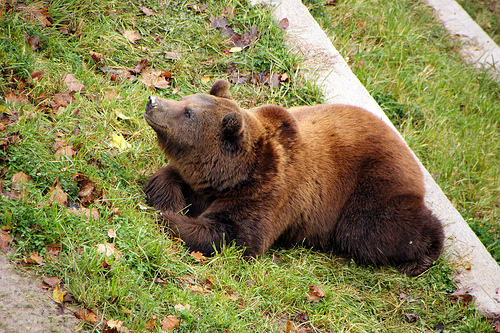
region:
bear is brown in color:
[142, 99, 431, 254]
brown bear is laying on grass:
[138, 91, 430, 265]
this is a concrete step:
[301, 45, 343, 81]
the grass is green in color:
[21, 58, 91, 159]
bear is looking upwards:
[148, 90, 248, 151]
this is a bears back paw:
[388, 250, 435, 276]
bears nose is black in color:
[142, 93, 158, 108]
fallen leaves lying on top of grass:
[97, 61, 177, 82]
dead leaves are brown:
[207, 13, 247, 49]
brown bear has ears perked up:
[211, 80, 249, 139]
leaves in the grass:
[171, 11, 283, 71]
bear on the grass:
[113, 89, 428, 306]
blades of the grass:
[207, 232, 245, 259]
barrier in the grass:
[278, 6, 377, 107]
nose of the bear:
[142, 91, 159, 111]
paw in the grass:
[146, 213, 213, 253]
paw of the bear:
[135, 217, 260, 254]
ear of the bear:
[214, 109, 251, 143]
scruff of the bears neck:
[236, 100, 305, 157]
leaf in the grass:
[60, 68, 88, 94]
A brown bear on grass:
[147, 97, 443, 276]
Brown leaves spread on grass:
[0, 1, 498, 331]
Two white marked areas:
[267, 0, 497, 331]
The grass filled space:
[2, 1, 499, 331]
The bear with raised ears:
[146, 80, 446, 276]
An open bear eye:
[185, 106, 195, 116]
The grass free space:
[0, 260, 76, 325]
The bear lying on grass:
[141, 80, 436, 266]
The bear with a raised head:
[145, 87, 440, 272]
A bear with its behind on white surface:
[146, 81, 443, 278]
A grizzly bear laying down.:
[143, 76, 443, 275]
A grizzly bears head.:
[145, 76, 254, 183]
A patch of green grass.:
[0, 0, 495, 332]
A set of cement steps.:
[256, 0, 499, 332]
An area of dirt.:
[0, 228, 82, 330]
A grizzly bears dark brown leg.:
[331, 189, 448, 279]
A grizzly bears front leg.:
[157, 189, 287, 257]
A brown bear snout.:
[142, 98, 178, 138]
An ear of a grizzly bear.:
[218, 109, 248, 147]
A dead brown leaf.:
[306, 283, 323, 303]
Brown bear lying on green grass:
[135, 75, 440, 270]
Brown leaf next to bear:
[135, 65, 170, 90]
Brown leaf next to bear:
[180, 240, 205, 260]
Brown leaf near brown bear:
[95, 235, 120, 255]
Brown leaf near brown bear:
[305, 280, 325, 300]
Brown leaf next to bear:
[200, 265, 210, 285]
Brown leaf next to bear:
[60, 65, 85, 85]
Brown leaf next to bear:
[440, 280, 475, 300]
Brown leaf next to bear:
[48, 137, 83, 157]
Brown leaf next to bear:
[37, 178, 67, 213]